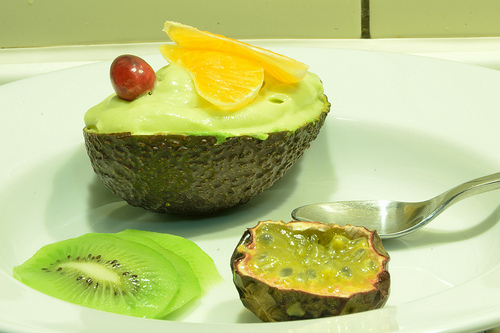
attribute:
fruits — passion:
[83, 61, 386, 306]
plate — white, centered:
[341, 43, 492, 329]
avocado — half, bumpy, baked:
[102, 92, 341, 192]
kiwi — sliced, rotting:
[46, 225, 213, 317]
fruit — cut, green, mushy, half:
[235, 215, 392, 317]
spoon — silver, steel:
[313, 188, 485, 220]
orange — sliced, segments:
[176, 30, 287, 100]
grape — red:
[101, 50, 158, 99]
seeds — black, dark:
[270, 257, 369, 276]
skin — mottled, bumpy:
[247, 291, 345, 319]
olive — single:
[97, 57, 148, 96]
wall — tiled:
[95, 1, 497, 46]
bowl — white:
[370, 57, 499, 275]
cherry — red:
[115, 61, 158, 91]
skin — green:
[121, 139, 306, 193]